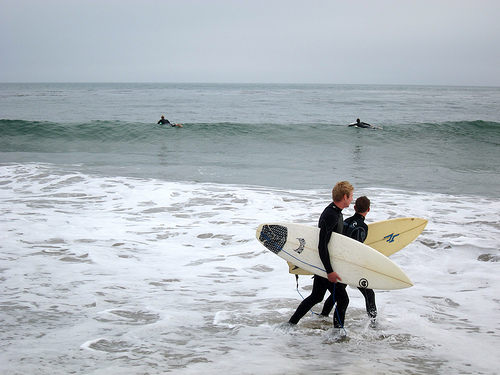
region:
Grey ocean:
[0, 83, 499, 373]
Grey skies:
[0, 2, 497, 85]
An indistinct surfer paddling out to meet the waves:
[149, 105, 183, 133]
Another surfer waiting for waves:
[346, 112, 386, 138]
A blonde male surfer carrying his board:
[255, 173, 416, 350]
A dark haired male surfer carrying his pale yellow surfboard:
[286, 195, 435, 335]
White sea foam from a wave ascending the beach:
[0, 162, 497, 372]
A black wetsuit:
[283, 201, 348, 332]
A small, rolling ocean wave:
[0, 110, 498, 155]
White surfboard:
[252, 213, 419, 298]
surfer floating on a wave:
[346, 117, 377, 132]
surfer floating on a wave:
[155, 113, 182, 129]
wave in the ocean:
[0, 117, 499, 147]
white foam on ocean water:
[1, 162, 498, 374]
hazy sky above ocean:
[0, 0, 495, 88]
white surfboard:
[256, 220, 414, 291]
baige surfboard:
[286, 215, 427, 273]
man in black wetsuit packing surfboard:
[258, 182, 414, 332]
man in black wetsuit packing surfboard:
[314, 197, 427, 319]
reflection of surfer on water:
[349, 141, 368, 170]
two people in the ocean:
[150, 113, 390, 138]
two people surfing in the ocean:
[146, 111, 396, 133]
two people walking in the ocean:
[297, 177, 389, 341]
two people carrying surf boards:
[275, 157, 432, 337]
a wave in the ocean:
[67, 113, 475, 182]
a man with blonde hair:
[328, 178, 353, 210]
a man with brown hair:
[353, 187, 377, 217]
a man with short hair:
[357, 184, 374, 219]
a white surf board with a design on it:
[261, 222, 418, 288]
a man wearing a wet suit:
[307, 177, 355, 332]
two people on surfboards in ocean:
[132, 98, 387, 148]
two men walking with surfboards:
[264, 164, 439, 343]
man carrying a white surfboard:
[256, 178, 417, 330]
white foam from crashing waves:
[41, 165, 168, 371]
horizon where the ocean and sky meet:
[103, 69, 319, 94]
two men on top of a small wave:
[133, 106, 410, 148]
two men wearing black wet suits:
[292, 171, 385, 331]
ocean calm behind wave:
[103, 83, 423, 105]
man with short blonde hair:
[292, 173, 355, 329]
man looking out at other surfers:
[346, 193, 385, 252]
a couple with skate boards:
[251, 182, 433, 342]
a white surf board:
[256, 221, 416, 293]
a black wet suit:
[306, 208, 346, 328]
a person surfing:
[153, 111, 178, 136]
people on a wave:
[2, 112, 495, 131]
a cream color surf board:
[287, 213, 424, 272]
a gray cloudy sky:
[13, 1, 489, 81]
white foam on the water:
[15, 176, 488, 366]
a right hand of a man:
[321, 268, 345, 288]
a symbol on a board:
[383, 232, 400, 242]